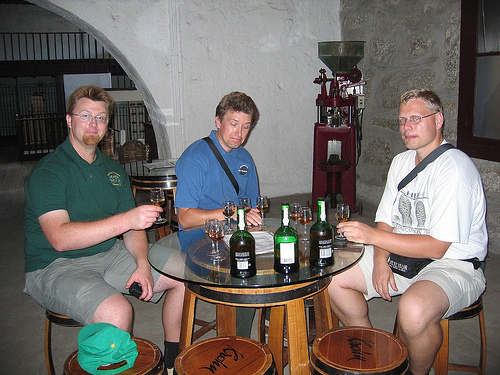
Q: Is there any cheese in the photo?
A: No, there is no cheese.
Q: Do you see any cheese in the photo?
A: No, there is no cheese.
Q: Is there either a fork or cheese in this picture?
A: No, there are no cheese or forks.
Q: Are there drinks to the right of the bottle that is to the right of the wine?
A: Yes, there is a drink to the right of the bottle.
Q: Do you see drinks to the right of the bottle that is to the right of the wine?
A: Yes, there is a drink to the right of the bottle.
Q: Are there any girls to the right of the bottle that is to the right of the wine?
A: No, there is a drink to the right of the bottle.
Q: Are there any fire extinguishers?
A: No, there are no fire extinguishers.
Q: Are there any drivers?
A: No, there are no drivers.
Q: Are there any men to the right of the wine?
A: Yes, there is a man to the right of the wine.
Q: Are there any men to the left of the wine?
A: No, the man is to the right of the wine.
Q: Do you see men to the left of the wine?
A: No, the man is to the right of the wine.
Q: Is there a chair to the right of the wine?
A: No, there is a man to the right of the wine.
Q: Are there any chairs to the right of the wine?
A: No, there is a man to the right of the wine.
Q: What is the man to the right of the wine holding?
A: The man is holding the glass.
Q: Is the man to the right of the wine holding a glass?
A: Yes, the man is holding a glass.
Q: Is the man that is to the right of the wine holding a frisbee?
A: No, the man is holding a glass.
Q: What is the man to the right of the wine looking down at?
A: The man is looking down at the glass.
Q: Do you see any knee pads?
A: No, there are no knee pads.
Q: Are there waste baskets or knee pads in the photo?
A: No, there are no knee pads or waste baskets.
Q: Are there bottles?
A: Yes, there is a bottle.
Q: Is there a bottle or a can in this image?
A: Yes, there is a bottle.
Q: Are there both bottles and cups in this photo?
A: No, there is a bottle but no cups.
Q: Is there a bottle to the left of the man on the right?
A: Yes, there is a bottle to the left of the man.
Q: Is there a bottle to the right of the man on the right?
A: No, the bottle is to the left of the man.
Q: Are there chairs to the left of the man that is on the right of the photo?
A: No, there is a bottle to the left of the man.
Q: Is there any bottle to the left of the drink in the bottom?
A: Yes, there is a bottle to the left of the drink.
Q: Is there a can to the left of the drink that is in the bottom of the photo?
A: No, there is a bottle to the left of the drink.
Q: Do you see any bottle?
A: Yes, there is a bottle.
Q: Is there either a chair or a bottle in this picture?
A: Yes, there is a bottle.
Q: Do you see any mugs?
A: No, there are no mugs.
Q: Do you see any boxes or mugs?
A: No, there are no mugs or boxes.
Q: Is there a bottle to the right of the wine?
A: Yes, there is a bottle to the right of the wine.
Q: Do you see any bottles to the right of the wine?
A: Yes, there is a bottle to the right of the wine.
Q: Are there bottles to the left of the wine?
A: No, the bottle is to the right of the wine.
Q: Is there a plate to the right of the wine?
A: No, there is a bottle to the right of the wine.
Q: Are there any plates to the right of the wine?
A: No, there is a bottle to the right of the wine.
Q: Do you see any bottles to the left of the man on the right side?
A: Yes, there is a bottle to the left of the man.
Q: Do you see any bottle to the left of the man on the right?
A: Yes, there is a bottle to the left of the man.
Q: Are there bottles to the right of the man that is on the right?
A: No, the bottle is to the left of the man.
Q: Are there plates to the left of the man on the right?
A: No, there is a bottle to the left of the man.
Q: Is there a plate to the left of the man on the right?
A: No, there is a bottle to the left of the man.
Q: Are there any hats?
A: Yes, there is a hat.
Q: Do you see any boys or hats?
A: Yes, there is a hat.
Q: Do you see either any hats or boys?
A: Yes, there is a hat.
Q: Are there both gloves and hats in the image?
A: No, there is a hat but no gloves.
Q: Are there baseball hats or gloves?
A: Yes, there is a baseball hat.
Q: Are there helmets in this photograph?
A: No, there are no helmets.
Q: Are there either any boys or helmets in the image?
A: No, there are no helmets or boys.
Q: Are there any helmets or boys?
A: No, there are no helmets or boys.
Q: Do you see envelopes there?
A: No, there are no envelopes.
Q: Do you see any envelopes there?
A: No, there are no envelopes.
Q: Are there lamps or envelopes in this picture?
A: No, there are no envelopes or lamps.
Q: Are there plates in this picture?
A: No, there are no plates.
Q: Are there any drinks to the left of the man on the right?
A: Yes, there is a drink to the left of the man.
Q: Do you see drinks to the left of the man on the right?
A: Yes, there is a drink to the left of the man.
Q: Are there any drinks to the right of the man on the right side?
A: No, the drink is to the left of the man.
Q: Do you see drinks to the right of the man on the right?
A: No, the drink is to the left of the man.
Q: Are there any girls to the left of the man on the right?
A: No, there is a drink to the left of the man.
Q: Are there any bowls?
A: No, there are no bowls.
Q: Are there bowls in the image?
A: No, there are no bowls.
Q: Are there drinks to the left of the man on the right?
A: Yes, there is a drink to the left of the man.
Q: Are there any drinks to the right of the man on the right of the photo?
A: No, the drink is to the left of the man.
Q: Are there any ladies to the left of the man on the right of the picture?
A: No, there is a drink to the left of the man.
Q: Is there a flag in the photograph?
A: No, there are no flags.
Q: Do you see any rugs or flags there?
A: No, there are no flags or rugs.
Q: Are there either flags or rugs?
A: No, there are no flags or rugs.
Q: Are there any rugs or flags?
A: No, there are no flags or rugs.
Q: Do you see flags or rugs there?
A: No, there are no flags or rugs.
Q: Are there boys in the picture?
A: No, there are no boys.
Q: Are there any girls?
A: No, there are no girls.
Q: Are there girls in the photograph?
A: No, there are no girls.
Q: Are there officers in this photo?
A: No, there are no officers.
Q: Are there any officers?
A: No, there are no officers.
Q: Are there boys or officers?
A: No, there are no officers or boys.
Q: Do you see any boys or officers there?
A: No, there are no officers or boys.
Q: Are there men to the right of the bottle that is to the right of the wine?
A: Yes, there is a man to the right of the bottle.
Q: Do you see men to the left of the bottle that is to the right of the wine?
A: No, the man is to the right of the bottle.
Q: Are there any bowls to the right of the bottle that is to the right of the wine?
A: No, there is a man to the right of the bottle.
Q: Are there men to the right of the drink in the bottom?
A: Yes, there is a man to the right of the drink.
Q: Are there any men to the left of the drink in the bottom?
A: No, the man is to the right of the drink.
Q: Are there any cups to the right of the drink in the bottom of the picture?
A: No, there is a man to the right of the drink.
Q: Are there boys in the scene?
A: No, there are no boys.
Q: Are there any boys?
A: No, there are no boys.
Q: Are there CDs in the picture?
A: No, there are no cds.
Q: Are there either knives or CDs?
A: No, there are no CDs or knives.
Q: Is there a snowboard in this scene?
A: No, there are no snowboards.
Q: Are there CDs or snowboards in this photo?
A: No, there are no snowboards or cds.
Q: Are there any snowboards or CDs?
A: No, there are no snowboards or cds.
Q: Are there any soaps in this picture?
A: No, there are no soaps.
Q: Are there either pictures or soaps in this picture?
A: No, there are no soaps or pictures.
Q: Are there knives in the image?
A: No, there are no knives.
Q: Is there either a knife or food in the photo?
A: No, there are no knives or food.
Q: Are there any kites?
A: No, there are no kites.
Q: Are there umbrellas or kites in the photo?
A: No, there are no kites or umbrellas.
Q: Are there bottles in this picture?
A: Yes, there is a bottle.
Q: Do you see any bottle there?
A: Yes, there is a bottle.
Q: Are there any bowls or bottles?
A: Yes, there is a bottle.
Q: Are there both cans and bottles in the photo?
A: No, there is a bottle but no cans.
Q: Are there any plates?
A: No, there are no plates.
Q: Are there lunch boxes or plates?
A: No, there are no plates or lunch boxes.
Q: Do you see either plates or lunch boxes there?
A: No, there are no plates or lunch boxes.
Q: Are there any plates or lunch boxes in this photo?
A: No, there are no plates or lunch boxes.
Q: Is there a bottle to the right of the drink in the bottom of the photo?
A: Yes, there is a bottle to the right of the drink.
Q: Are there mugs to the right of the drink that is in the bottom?
A: No, there is a bottle to the right of the drink.